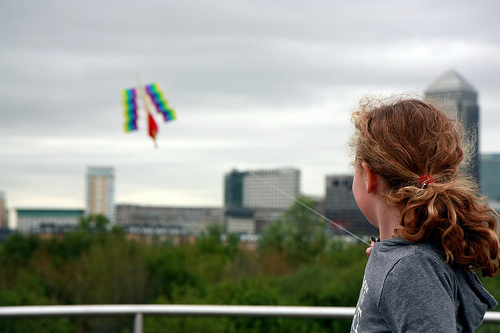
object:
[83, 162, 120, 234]
buildings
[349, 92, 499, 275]
hair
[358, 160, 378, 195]
ear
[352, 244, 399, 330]
chest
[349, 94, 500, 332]
person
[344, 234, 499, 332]
body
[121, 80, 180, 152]
kite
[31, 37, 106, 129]
air